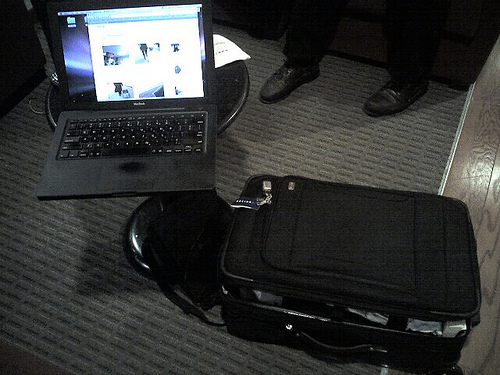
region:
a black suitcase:
[214, 164, 482, 373]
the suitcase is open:
[227, 270, 477, 342]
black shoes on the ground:
[260, 44, 441, 120]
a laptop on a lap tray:
[25, 7, 230, 206]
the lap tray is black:
[30, 39, 250, 140]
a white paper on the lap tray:
[207, 28, 254, 67]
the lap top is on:
[46, 2, 221, 195]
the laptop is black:
[35, 8, 225, 203]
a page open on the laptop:
[85, 12, 204, 97]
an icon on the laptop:
[64, 17, 79, 32]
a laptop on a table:
[28, 9, 229, 220]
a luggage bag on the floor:
[227, 143, 494, 374]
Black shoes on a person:
[249, 42, 446, 144]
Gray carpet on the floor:
[283, 101, 429, 187]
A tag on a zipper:
[228, 183, 263, 215]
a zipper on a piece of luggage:
[260, 182, 277, 208]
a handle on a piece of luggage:
[270, 323, 404, 360]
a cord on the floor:
[20, 92, 48, 121]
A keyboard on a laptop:
[55, 117, 202, 165]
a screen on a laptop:
[44, 7, 226, 108]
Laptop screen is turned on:
[49, 3, 218, 107]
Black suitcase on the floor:
[212, 173, 485, 372]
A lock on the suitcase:
[251, 174, 276, 205]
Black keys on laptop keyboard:
[53, 108, 210, 163]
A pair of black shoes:
[256, 56, 434, 120]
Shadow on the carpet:
[72, 129, 252, 301]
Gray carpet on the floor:
[1, 18, 470, 374]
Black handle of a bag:
[281, 318, 391, 369]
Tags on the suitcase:
[221, 191, 270, 210]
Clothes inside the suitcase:
[231, 278, 471, 343]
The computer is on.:
[42, 5, 228, 195]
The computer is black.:
[48, 8, 218, 194]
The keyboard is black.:
[65, 113, 209, 155]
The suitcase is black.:
[219, 162, 482, 362]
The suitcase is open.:
[218, 178, 483, 359]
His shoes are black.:
[255, 52, 440, 124]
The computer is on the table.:
[40, 1, 253, 177]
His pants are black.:
[276, 0, 449, 75]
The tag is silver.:
[231, 192, 260, 217]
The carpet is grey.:
[18, 102, 295, 374]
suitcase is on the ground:
[228, 175, 482, 365]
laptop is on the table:
[40, 10, 252, 190]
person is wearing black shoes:
[260, 55, 425, 135]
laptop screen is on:
[59, 3, 206, 106]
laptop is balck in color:
[45, 4, 221, 199]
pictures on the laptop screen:
[102, 38, 184, 98]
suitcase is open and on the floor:
[220, 253, 471, 348]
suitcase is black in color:
[230, 167, 482, 370]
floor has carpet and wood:
[378, 90, 499, 184]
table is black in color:
[49, 43, 254, 131]